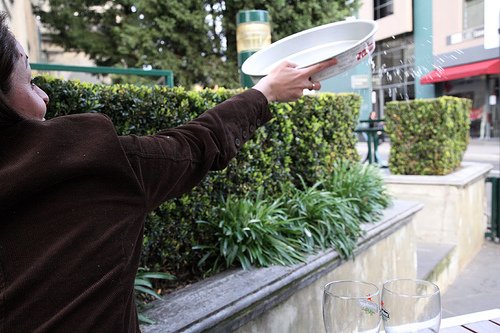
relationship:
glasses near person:
[300, 278, 411, 327] [26, 62, 118, 311]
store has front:
[404, 48, 486, 129] [445, 86, 496, 122]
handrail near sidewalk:
[86, 38, 174, 100] [321, 140, 489, 162]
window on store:
[372, 58, 402, 93] [404, 48, 486, 129]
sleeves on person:
[171, 97, 266, 168] [0, 12, 335, 333]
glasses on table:
[300, 278, 411, 327] [463, 302, 497, 321]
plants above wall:
[145, 73, 368, 223] [221, 270, 331, 324]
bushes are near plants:
[127, 101, 312, 234] [38, 81, 392, 280]